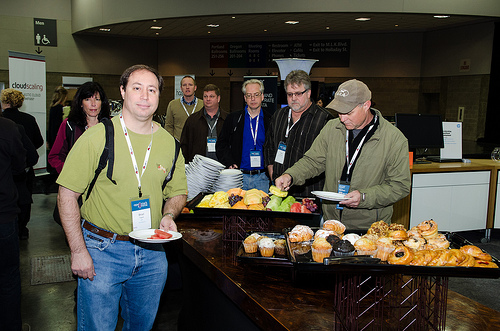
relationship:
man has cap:
[272, 80, 413, 234] [324, 80, 370, 113]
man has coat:
[272, 80, 413, 234] [285, 108, 412, 224]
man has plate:
[272, 80, 413, 234] [310, 190, 351, 205]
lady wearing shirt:
[48, 80, 112, 228] [47, 116, 88, 174]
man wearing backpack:
[53, 64, 189, 327] [81, 117, 181, 204]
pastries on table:
[238, 216, 494, 268] [161, 208, 497, 329]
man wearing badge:
[53, 64, 189, 327] [118, 110, 153, 234]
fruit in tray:
[182, 185, 321, 212] [184, 190, 322, 233]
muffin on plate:
[312, 240, 332, 263] [235, 230, 499, 278]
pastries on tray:
[238, 216, 494, 268] [275, 230, 498, 275]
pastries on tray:
[238, 216, 494, 268] [233, 213, 498, 285]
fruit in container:
[182, 185, 321, 212] [181, 186, 322, 233]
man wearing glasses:
[262, 71, 338, 223] [285, 90, 308, 98]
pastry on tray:
[243, 219, 495, 265] [235, 217, 498, 289]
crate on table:
[337, 266, 444, 329] [171, 220, 496, 330]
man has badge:
[53, 64, 189, 327] [119, 119, 153, 240]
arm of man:
[55, 117, 105, 280] [53, 64, 189, 327]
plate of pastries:
[248, 234, 477, 279] [238, 216, 494, 268]